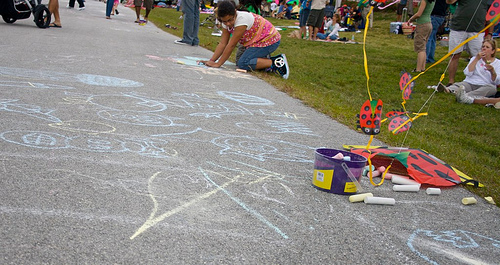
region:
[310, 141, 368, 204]
purple plastic bucket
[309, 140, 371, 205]
container full of chalk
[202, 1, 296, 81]
young girl wearing denim capris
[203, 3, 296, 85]
young girl wearing black and white shoes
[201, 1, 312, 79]
young girl drawing on road with chalk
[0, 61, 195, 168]
chalk drawings on pavement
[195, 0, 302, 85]
young girl wearing pink and white top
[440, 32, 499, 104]
woman wearing white top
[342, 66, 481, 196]
ladybug themed kite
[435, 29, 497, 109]
lady blowing bubbles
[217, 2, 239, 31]
the head of a girl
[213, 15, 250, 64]
the arm of a girl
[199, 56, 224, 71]
the hand of a girl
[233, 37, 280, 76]
the arm of a girl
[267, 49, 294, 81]
a black and white shoe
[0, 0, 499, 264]
gray asphalt pavement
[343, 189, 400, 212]
sidewalk chalk on the ground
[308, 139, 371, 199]
a purple plastic bucket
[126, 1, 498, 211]
a patch of green grass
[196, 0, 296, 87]
a girl on the ground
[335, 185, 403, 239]
chalk on the pavement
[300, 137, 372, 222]
a purple bucket filled with chalk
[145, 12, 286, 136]
girl drawing with chalk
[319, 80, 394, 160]
a small kite shaped like a lady bug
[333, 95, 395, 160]
red black and green lady bug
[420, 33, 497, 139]
woman sitting on the grass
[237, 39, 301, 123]
a black and white shoe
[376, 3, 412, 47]
a gray and white cooler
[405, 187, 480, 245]
a piece of yellow chalk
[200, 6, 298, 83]
a girl drawing with chalk on the ground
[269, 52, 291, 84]
black sneakers with a peace symbol on the young girl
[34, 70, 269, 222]
chalk drawings on the ground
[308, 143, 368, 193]
a purple bucket of chalk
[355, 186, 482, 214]
several pieces of chalk on the ground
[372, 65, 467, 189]
a butterfly shaped kite on the ground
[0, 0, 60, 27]
the tires of a stroller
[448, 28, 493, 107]
an older woman sitting on the grass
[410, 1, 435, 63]
a person wearing a green tank stop and khaki shorts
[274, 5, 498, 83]
a bunch of people on the grass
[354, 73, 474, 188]
ladybug kites on ground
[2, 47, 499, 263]
people chalking on concrete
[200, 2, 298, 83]
girl kneeling on grass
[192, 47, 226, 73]
hands leaning on concrete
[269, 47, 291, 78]
black shoes with peace signs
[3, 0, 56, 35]
partial view of stroller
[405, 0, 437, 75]
green shirt and khaki pants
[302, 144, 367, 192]
purple bucket of chalk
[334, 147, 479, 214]
pieces of chalk next to bucket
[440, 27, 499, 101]
woman sitting and eating on grass